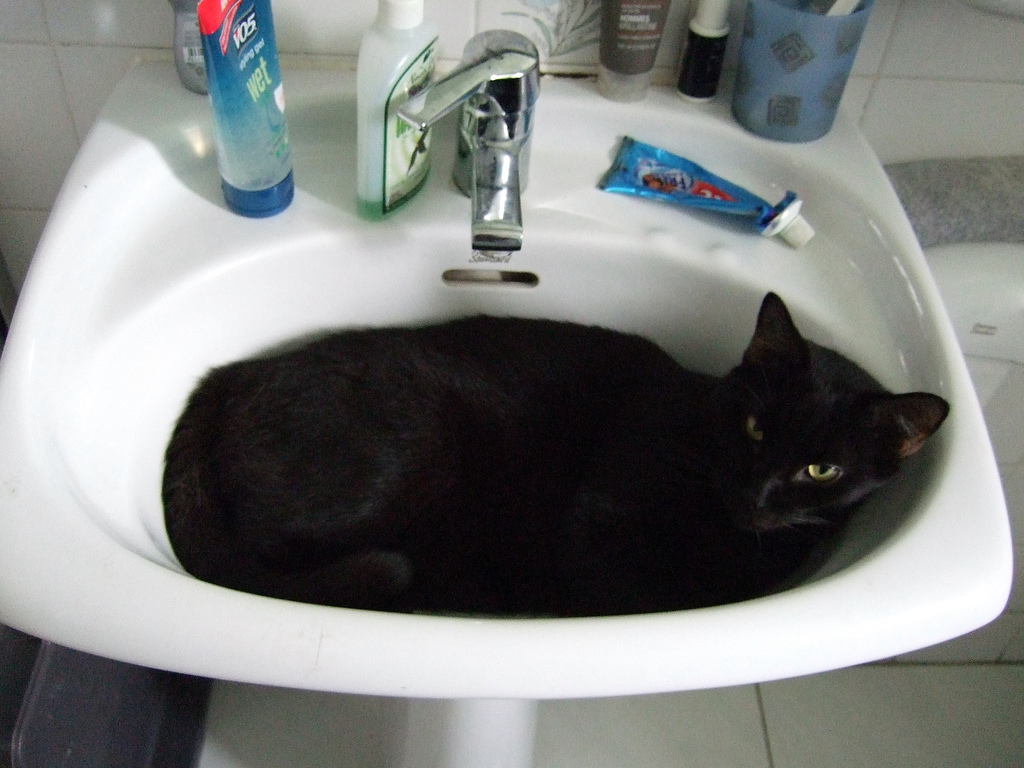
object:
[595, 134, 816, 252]
toothpaste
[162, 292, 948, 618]
cat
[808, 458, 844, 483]
eyes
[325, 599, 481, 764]
incorrect image